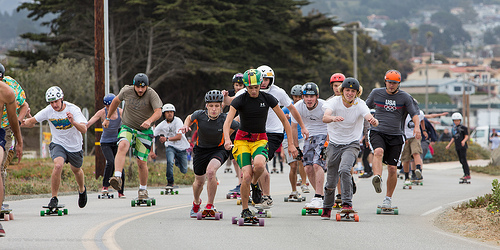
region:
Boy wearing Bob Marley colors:
[237, 65, 284, 230]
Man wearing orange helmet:
[381, 67, 404, 91]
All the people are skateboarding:
[2, 57, 486, 247]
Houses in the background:
[404, 41, 498, 146]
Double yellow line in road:
[78, 191, 203, 221]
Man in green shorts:
[118, 122, 155, 167]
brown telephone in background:
[92, 2, 110, 178]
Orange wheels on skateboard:
[334, 208, 369, 226]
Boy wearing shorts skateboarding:
[232, 152, 279, 223]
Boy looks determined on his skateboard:
[207, 101, 221, 117]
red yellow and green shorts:
[227, 123, 272, 186]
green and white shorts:
[112, 120, 162, 165]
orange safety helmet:
[380, 59, 407, 99]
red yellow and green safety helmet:
[230, 65, 275, 93]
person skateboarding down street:
[442, 101, 499, 203]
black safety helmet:
[126, 65, 159, 108]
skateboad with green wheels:
[302, 195, 327, 228]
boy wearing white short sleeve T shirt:
[327, 91, 373, 141]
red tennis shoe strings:
[186, 195, 222, 220]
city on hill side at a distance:
[408, 23, 494, 125]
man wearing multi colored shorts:
[235, 133, 270, 161]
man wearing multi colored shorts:
[123, 127, 155, 159]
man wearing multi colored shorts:
[368, 132, 409, 162]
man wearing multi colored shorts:
[155, 144, 193, 190]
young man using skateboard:
[38, 202, 78, 222]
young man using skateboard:
[135, 197, 159, 214]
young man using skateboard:
[300, 202, 325, 222]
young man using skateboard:
[377, 203, 404, 220]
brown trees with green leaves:
[119, 10, 319, 56]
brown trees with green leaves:
[388, 22, 460, 47]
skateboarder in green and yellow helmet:
[224, 69, 296, 226]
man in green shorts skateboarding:
[104, 72, 166, 207]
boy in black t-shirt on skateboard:
[445, 112, 474, 186]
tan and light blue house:
[406, 77, 483, 96]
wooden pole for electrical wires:
[89, 0, 115, 92]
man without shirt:
[0, 75, 23, 234]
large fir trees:
[15, 2, 379, 79]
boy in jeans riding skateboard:
[155, 104, 190, 194]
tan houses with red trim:
[407, 51, 491, 81]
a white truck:
[467, 124, 499, 151]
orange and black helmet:
[372, 60, 412, 106]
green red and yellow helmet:
[223, 67, 265, 112]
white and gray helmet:
[35, 79, 65, 105]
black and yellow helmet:
[333, 70, 365, 103]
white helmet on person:
[440, 110, 467, 132]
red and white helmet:
[324, 66, 349, 84]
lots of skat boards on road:
[145, 180, 413, 243]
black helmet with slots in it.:
[189, 85, 224, 110]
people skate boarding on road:
[17, 57, 415, 243]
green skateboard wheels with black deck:
[12, 195, 66, 227]